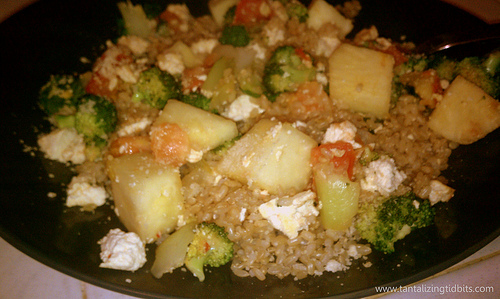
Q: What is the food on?
A: Plate.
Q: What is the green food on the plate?
A: Broccoli.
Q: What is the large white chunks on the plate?
A: Potatoes.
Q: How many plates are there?
A: One.